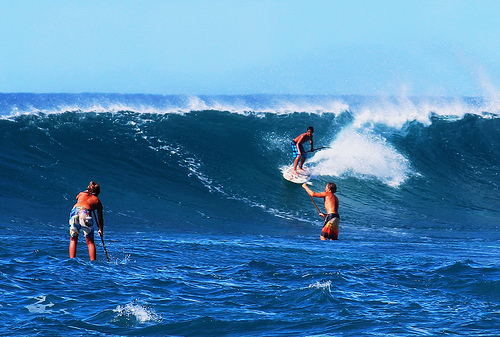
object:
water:
[0, 154, 499, 337]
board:
[283, 164, 312, 184]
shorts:
[321, 213, 341, 241]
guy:
[290, 126, 315, 175]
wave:
[4, 89, 499, 186]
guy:
[68, 181, 106, 262]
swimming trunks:
[69, 207, 96, 238]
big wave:
[5, 104, 497, 196]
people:
[67, 126, 339, 261]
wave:
[87, 284, 152, 333]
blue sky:
[0, 1, 498, 98]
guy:
[301, 183, 339, 240]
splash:
[310, 120, 418, 187]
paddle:
[309, 196, 325, 216]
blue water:
[0, 95, 499, 337]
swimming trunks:
[290, 140, 307, 158]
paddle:
[92, 211, 110, 263]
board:
[34, 251, 125, 266]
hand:
[302, 183, 307, 188]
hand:
[318, 212, 326, 216]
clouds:
[0, 0, 499, 94]